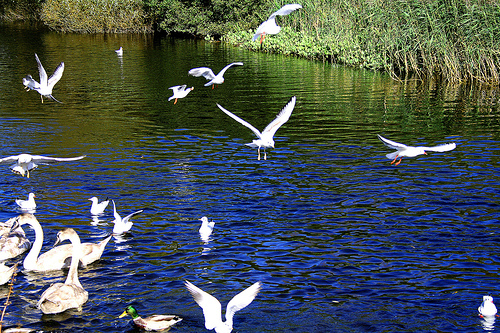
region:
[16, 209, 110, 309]
swan swimming in the water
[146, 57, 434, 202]
many birds are flying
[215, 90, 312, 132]
wings of the bird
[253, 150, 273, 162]
leg of the bird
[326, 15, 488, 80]
plants and trees near the water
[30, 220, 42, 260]
neck of the swan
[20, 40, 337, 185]
many birds are flying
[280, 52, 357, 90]
reflection of plants in the water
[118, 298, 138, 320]
head of the bird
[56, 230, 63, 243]
eyes of the bird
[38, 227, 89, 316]
wild geese in the pond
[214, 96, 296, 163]
seagulls hovering over the pond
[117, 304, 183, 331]
a mallard duck in the pond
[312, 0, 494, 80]
tall grass on the bank of the pond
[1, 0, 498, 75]
aquatic plants growing on the pond shoreline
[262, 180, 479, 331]
deep blue water in the pond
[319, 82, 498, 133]
a reflection of the plants on the water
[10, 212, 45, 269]
a goose's long neck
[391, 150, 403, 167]
a seagulls orange feet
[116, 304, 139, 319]
a mallard ducks green head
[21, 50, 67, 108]
white bird is next to white bird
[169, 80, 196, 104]
white bird is next to white bird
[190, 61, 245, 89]
white bird is next to white bird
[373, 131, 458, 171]
white bird is next to white bird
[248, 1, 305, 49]
white bird is next to white bird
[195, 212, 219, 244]
white bird is next to white bird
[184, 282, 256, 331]
white bird is next to white bird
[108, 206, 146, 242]
white bird is next to white bird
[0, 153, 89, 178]
white bird is next to white bird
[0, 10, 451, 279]
birds flying over water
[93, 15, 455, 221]
flock of birds flying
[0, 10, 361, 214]
birds flying together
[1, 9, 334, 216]
flock of white birds flying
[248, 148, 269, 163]
yellow legs of bird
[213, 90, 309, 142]
white wings of bird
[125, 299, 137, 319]
green head of bird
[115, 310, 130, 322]
yellow beak of bird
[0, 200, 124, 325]
geese in the water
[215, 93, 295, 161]
a bird is in flight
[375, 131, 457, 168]
a bird is in flight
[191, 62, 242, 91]
a bird is in flight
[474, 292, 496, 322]
a bird sitting in water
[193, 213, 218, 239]
a bird sitting in water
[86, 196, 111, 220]
a bird sitting in water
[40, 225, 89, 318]
a bird with a long neck sitting in water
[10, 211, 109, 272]
a bird with a long neck sitting in water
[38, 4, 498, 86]
bushes along the water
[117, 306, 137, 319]
green head of a mallard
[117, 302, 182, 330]
The duck with the green face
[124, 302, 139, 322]
The green face of the duck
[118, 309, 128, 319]
The yellow bill of the duck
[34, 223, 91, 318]
The swan swimming beside the duck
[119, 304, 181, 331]
A bird swimming on some water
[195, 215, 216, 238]
A bird swimming on some water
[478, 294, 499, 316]
A bird swimming on some water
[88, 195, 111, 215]
A bird swimming on some water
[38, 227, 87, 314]
A bird swimming on some water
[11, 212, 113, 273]
A bird swimming on some water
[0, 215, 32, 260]
A bird swimming on some water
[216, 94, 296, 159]
A bird flying near some water